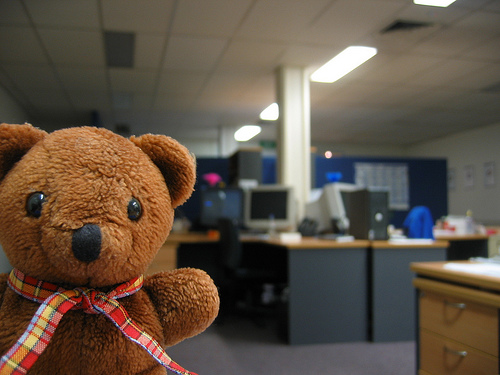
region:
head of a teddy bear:
[0, 101, 210, 287]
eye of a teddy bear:
[23, 179, 70, 215]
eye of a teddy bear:
[120, 195, 150, 224]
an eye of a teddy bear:
[19, 173, 57, 221]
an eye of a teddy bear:
[123, 185, 149, 218]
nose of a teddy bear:
[65, 222, 111, 259]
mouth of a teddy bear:
[20, 219, 146, 295]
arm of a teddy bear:
[160, 258, 245, 335]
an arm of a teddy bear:
[148, 238, 231, 348]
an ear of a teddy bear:
[118, 128, 213, 212]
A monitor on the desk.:
[239, 173, 304, 238]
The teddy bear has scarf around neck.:
[8, 272, 169, 332]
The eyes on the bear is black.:
[16, 188, 155, 228]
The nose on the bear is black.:
[77, 219, 97, 255]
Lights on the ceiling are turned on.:
[216, 94, 283, 154]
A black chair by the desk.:
[213, 222, 258, 294]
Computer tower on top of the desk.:
[355, 184, 395, 244]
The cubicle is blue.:
[341, 152, 440, 207]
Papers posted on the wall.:
[451, 150, 499, 182]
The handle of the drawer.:
[441, 296, 462, 313]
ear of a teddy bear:
[5, 96, 70, 173]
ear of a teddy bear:
[125, 127, 231, 207]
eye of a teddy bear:
[19, 196, 60, 233]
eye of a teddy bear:
[105, 188, 152, 227]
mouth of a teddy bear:
[14, 253, 137, 299]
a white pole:
[277, 58, 313, 206]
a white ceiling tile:
[159, 33, 221, 76]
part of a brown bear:
[0, 121, 220, 373]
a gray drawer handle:
[434, 340, 471, 357]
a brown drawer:
[415, 284, 498, 342]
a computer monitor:
[245, 185, 295, 227]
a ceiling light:
[303, 41, 375, 86]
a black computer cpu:
[352, 182, 394, 242]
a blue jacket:
[404, 205, 436, 239]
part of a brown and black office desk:
[250, 225, 367, 345]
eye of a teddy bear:
[124, 191, 156, 216]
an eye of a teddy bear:
[30, 187, 55, 221]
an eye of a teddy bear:
[121, 184, 167, 224]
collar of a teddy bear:
[12, 255, 164, 325]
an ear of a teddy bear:
[3, 109, 58, 179]